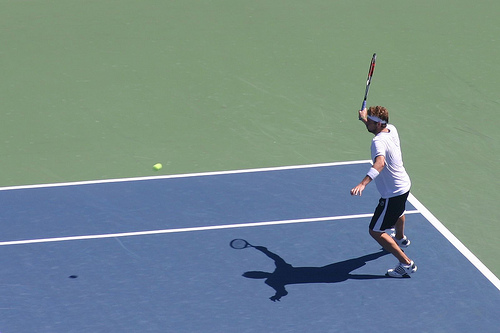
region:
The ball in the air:
[150, 160, 167, 175]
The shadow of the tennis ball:
[60, 268, 82, 283]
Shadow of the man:
[226, 228, 413, 307]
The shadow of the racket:
[226, 234, 260, 251]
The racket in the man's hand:
[358, 46, 384, 123]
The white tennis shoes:
[380, 230, 420, 281]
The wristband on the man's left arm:
[365, 164, 379, 183]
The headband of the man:
[365, 111, 390, 125]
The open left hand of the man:
[348, 183, 368, 198]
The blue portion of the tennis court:
[0, 153, 499, 331]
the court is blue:
[153, 231, 350, 306]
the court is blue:
[182, 238, 287, 306]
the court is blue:
[80, 175, 257, 313]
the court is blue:
[126, 185, 220, 310]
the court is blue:
[119, 164, 209, 259]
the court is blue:
[127, 178, 181, 230]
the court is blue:
[143, 231, 180, 276]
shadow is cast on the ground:
[215, 170, 397, 328]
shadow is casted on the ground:
[215, 171, 397, 315]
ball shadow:
[62, 258, 114, 303]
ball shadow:
[37, 241, 128, 302]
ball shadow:
[62, 247, 99, 319]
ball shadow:
[55, 260, 136, 327]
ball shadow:
[62, 270, 90, 287]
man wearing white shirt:
[269, 70, 457, 317]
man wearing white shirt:
[340, 82, 411, 267]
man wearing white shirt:
[345, 67, 487, 325]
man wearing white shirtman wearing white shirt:
[345, 114, 430, 236]